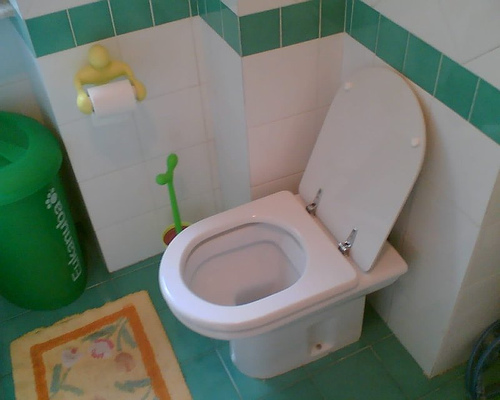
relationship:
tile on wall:
[411, 45, 444, 87] [240, 8, 315, 127]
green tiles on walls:
[9, 9, 499, 150] [3, 4, 496, 379]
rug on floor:
[13, 297, 184, 399] [14, 301, 486, 398]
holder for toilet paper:
[70, 43, 140, 122] [83, 76, 139, 124]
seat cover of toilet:
[296, 65, 431, 271] [84, 67, 495, 323]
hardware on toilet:
[304, 194, 359, 257] [134, 73, 439, 372]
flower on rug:
[88, 322, 119, 366] [16, 283, 189, 399]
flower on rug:
[106, 315, 136, 381] [16, 283, 189, 399]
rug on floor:
[7, 286, 192, 400] [233, 386, 325, 398]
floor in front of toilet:
[233, 386, 325, 398] [167, 60, 402, 325]